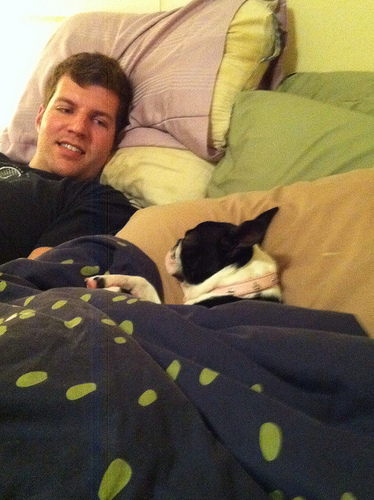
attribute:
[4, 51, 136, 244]
man — looking, smiling, laying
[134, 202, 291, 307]
dog — resting, black, white, laying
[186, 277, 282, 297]
collar — pink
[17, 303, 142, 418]
designs — green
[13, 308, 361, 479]
blanket — black, blue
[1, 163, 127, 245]
shirt — black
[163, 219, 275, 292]
head — black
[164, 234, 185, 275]
nose — white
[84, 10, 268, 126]
case — pink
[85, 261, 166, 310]
paw — pink, black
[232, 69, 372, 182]
pillows — stacked, green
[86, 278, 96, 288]
pad — pink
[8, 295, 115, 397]
dots — green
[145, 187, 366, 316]
pillow — tan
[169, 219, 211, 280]
face — black, white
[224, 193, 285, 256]
ears — black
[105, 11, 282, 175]
pillow — white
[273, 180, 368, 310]
case — brown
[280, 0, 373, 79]
wall — yellow, creme